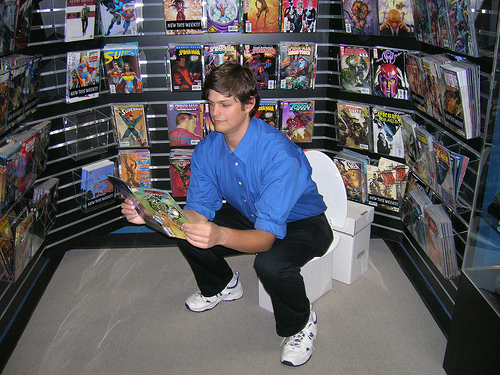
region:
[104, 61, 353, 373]
Man sits toilet seat read comic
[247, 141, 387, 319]
Fake toilet available store seat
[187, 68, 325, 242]
Bright blue shirt rolled sleeves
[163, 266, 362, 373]
Blue trimmed white sneakers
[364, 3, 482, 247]
Racks right comic books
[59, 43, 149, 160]
Super comic book heros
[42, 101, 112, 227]
Metal racks plexiglass bins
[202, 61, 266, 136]
Boy smiles enjoys comic book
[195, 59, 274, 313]
Curly brown hair black pants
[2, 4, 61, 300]
Left racks deep comic titles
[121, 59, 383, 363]
a man sitting down on a toilet.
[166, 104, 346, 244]
a shiny blue shirt.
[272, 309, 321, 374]
the left foot of a man.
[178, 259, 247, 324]
the right foot of a man.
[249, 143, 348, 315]
a baby sized toilet.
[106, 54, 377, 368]
a man defecating in a crowded comic book store.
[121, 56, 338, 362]
A man child using a toilet in front of everyone.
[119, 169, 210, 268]
hands holding a comic book.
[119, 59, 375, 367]
A man child reading a comic.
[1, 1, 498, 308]
a shelf with lots of comics.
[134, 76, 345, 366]
man in blue shirt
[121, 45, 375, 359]
man has brown hair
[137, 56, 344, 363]
man is wearing black pants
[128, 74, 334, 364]
white shoes of a man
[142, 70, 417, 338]
man holding comic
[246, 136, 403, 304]
white toilet by white box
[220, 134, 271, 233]
white buttons on blue shirt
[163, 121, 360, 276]
blue long sleeved shirt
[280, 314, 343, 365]
shoe with white and black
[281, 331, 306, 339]
white laces of shoes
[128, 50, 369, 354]
man sitting on toilet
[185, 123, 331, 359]
man in black pants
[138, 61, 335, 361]
man in white shoes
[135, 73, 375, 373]
man on white toilet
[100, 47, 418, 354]
man looking at comic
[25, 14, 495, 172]
comics on bathroom wall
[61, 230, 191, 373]
grey floor of room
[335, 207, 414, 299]
white box behind toilet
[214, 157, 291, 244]
white buttons on blue shirt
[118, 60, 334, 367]
Young man sitting on unconnected toilet in comic book room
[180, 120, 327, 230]
Blue shirt on young man reading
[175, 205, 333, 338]
Black pants worn by young man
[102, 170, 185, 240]
Comic book being read by young man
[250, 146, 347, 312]
Unconnected white toilet under young man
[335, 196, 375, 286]
White box in comic book room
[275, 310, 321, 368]
White and black shoe worn by young man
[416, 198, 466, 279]
Rack of comic books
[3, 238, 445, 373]
Gray floor in comic book room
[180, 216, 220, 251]
Young man's hand holding comic book